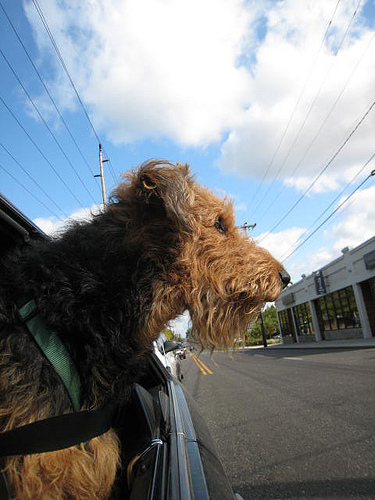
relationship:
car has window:
[0, 196, 245, 499] [2, 201, 179, 499]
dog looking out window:
[0, 156, 292, 496] [2, 201, 179, 499]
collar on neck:
[13, 293, 87, 412] [1, 212, 193, 411]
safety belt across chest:
[0, 390, 118, 455] [3, 388, 121, 499]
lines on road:
[182, 347, 211, 379] [173, 342, 374, 498]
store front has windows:
[270, 237, 374, 349] [278, 277, 375, 345]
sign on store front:
[279, 290, 296, 307] [270, 237, 374, 349]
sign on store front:
[311, 270, 329, 297] [270, 237, 374, 349]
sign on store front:
[360, 248, 374, 273] [270, 237, 374, 349]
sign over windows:
[279, 290, 296, 307] [278, 277, 375, 345]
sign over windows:
[311, 270, 329, 297] [278, 277, 375, 345]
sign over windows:
[360, 248, 374, 273] [278, 277, 375, 345]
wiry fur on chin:
[188, 295, 264, 362] [197, 286, 265, 315]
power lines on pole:
[1, 0, 122, 238] [92, 143, 114, 211]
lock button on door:
[134, 460, 152, 478] [133, 374, 244, 499]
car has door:
[0, 196, 245, 499] [133, 374, 244, 499]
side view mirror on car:
[160, 337, 180, 356] [152, 329, 184, 374]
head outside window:
[79, 160, 292, 357] [2, 201, 179, 499]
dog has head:
[0, 156, 292, 496] [79, 160, 292, 357]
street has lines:
[173, 343, 374, 500] [187, 347, 213, 378]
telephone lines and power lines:
[235, 102, 374, 267] [1, 0, 122, 238]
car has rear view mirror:
[152, 329, 184, 374] [160, 338, 180, 354]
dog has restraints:
[0, 156, 292, 496] [4, 288, 122, 454]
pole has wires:
[92, 143, 114, 211] [0, 1, 121, 241]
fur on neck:
[80, 312, 178, 408] [1, 212, 193, 411]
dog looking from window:
[0, 156, 292, 496] [2, 201, 179, 499]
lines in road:
[182, 347, 211, 379] [173, 342, 374, 498]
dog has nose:
[0, 156, 292, 496] [274, 265, 292, 289]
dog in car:
[0, 156, 292, 496] [0, 196, 245, 499]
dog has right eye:
[0, 156, 292, 496] [209, 211, 231, 235]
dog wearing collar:
[0, 156, 292, 496] [13, 293, 87, 412]